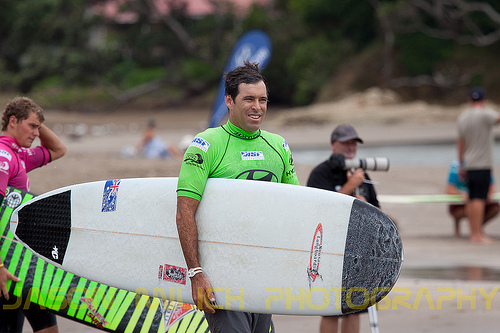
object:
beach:
[399, 237, 496, 319]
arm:
[26, 124, 68, 173]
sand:
[403, 240, 497, 324]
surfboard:
[0, 178, 400, 332]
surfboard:
[10, 176, 404, 315]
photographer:
[306, 121, 382, 332]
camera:
[340, 156, 391, 174]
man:
[175, 59, 302, 332]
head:
[224, 65, 269, 131]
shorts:
[203, 308, 272, 333]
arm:
[173, 133, 209, 275]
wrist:
[186, 265, 205, 280]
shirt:
[176, 122, 308, 201]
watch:
[186, 267, 202, 277]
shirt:
[0, 134, 52, 202]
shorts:
[0, 293, 55, 332]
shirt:
[306, 154, 381, 211]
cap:
[329, 124, 364, 144]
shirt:
[456, 107, 497, 168]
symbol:
[157, 262, 190, 285]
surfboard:
[0, 186, 275, 331]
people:
[0, 63, 499, 332]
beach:
[32, 118, 499, 331]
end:
[390, 216, 404, 304]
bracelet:
[187, 267, 207, 276]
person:
[454, 88, 499, 243]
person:
[137, 117, 159, 155]